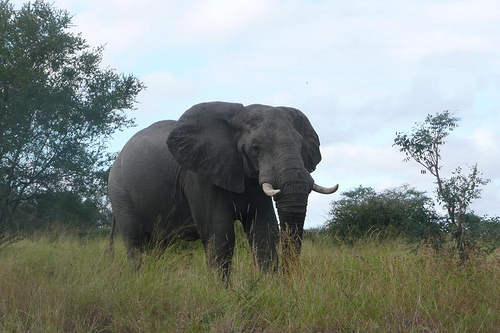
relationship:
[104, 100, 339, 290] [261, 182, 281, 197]
elephant has right tusk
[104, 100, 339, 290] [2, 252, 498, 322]
elephant on grass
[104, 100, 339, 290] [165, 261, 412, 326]
elephant on grass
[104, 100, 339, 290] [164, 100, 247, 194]
elephant has ear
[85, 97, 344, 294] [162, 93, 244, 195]
elephant has ear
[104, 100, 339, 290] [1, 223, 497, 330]
elephant on grass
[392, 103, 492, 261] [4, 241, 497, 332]
tree on grass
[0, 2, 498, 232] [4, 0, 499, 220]
sky with clouds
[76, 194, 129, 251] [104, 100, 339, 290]
tail of elephant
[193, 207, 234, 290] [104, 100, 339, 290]
right leg of elephant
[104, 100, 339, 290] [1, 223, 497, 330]
elephant standing in grass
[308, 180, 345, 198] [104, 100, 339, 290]
tusk on elephant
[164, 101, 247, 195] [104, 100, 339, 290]
ear on elephant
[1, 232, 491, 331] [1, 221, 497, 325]
grass in field